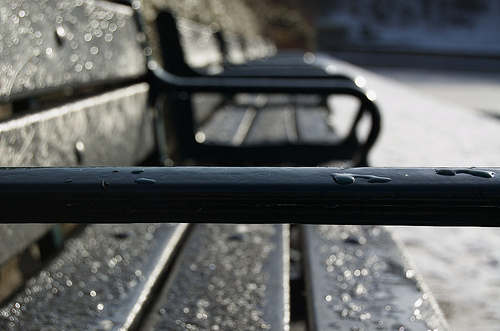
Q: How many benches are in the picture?
A: Three.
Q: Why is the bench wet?
A: Because it was raining.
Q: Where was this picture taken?
A: Outside by bench.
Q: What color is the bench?
A: Black.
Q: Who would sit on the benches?
A: People.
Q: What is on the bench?
A: Water.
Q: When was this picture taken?
A: During the day.